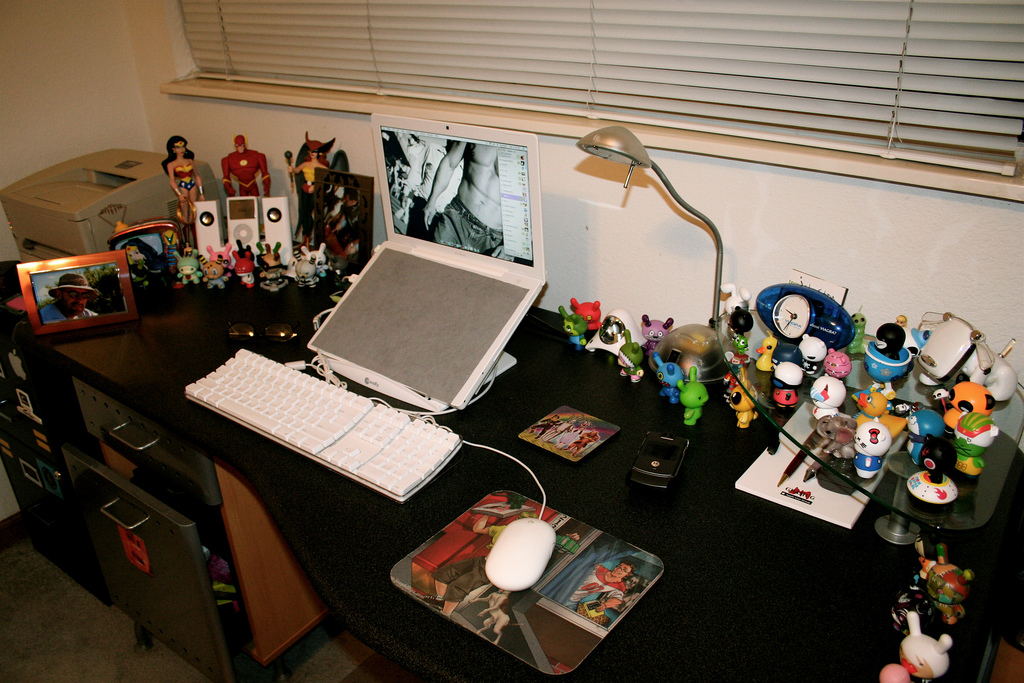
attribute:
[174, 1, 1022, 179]
blinds — white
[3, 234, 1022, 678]
desk — black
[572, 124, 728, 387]
lamp — silver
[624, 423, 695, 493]
cellphone — flip-style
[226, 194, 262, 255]
ipod — plays music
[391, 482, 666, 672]
mouse — white 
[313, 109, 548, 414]
laptop — white 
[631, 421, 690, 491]
phone — black 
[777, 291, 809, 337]
clock — tells time, blue 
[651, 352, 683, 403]
figurine — green 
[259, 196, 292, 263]
speaker — white 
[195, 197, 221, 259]
speaker — white 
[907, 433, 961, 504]
figurine — small 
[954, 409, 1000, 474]
figurine — small 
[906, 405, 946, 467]
figurine — small 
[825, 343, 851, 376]
figurine — small 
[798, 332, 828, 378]
figurine — small 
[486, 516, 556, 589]
mouse — white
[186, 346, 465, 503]
keyboard — white